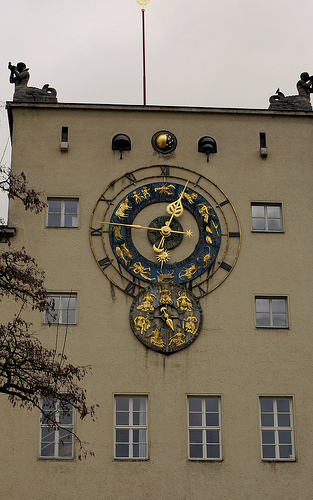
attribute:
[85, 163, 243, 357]
clock — large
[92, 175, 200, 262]
hands — GOLD 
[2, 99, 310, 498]
building — beige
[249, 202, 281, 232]
window — small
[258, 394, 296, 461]
window — square 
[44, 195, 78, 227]
window — small, square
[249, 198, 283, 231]
window — small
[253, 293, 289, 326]
window — small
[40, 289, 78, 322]
window — small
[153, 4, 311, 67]
sky — dark, white, gray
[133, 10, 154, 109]
rod — red, lightning 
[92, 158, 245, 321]
clock — large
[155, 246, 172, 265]
sun figure — golden 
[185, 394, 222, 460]
window — rectangular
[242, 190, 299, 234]
window — square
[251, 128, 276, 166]
buttress — small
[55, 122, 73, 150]
buttress — small